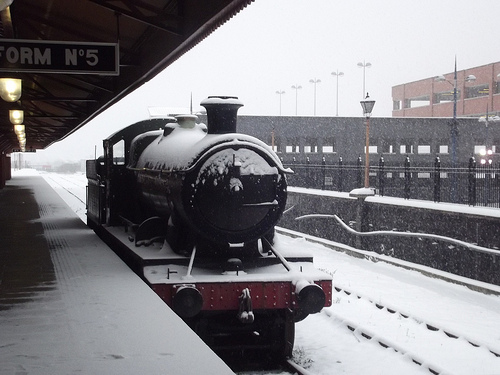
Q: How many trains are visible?
A: 1.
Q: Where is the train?
A: On the track.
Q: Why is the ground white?
A: It has snowed.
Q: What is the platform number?
A: 5.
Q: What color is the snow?
A: White.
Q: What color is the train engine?
A: Black.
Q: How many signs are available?
A: 1.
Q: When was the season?
A: Winter.